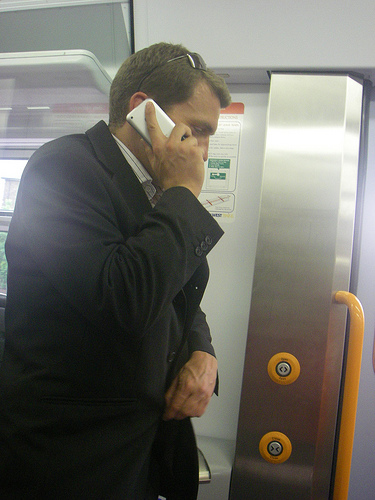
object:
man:
[0, 41, 232, 499]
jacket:
[0, 121, 225, 499]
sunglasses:
[110, 51, 207, 103]